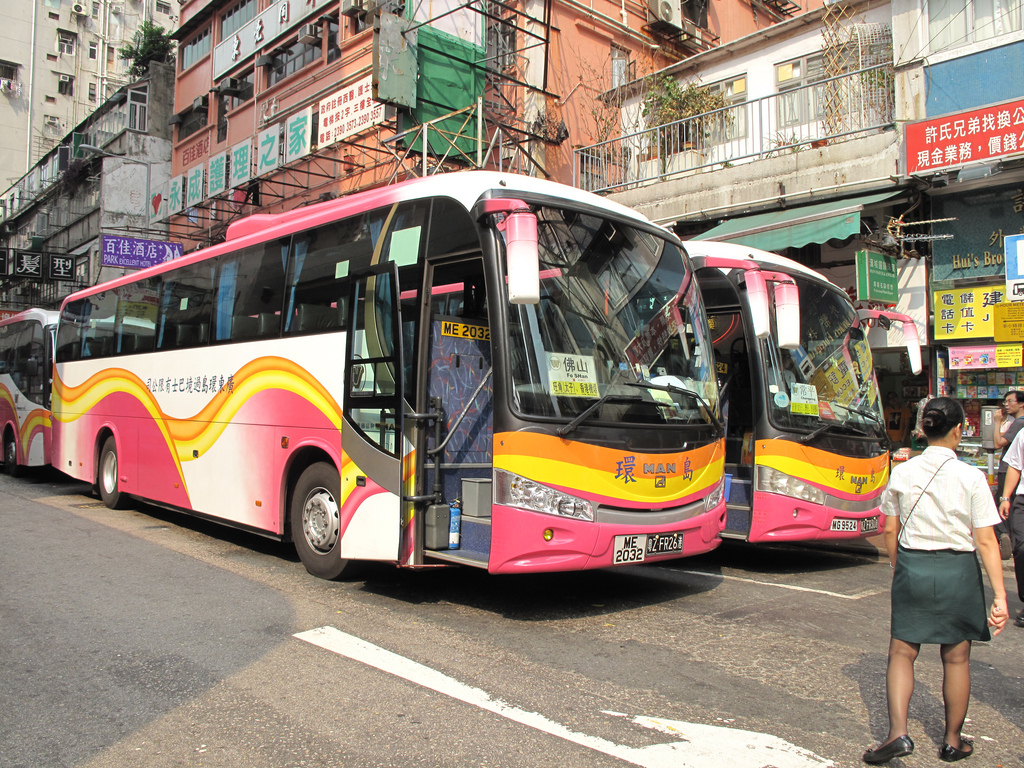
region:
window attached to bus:
[494, 202, 713, 431]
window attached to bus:
[753, 267, 884, 438]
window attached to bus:
[225, 238, 301, 333]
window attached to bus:
[156, 272, 232, 349]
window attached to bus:
[113, 276, 170, 346]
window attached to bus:
[60, 301, 98, 355]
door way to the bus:
[420, 251, 515, 562]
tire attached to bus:
[294, 460, 349, 575]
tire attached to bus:
[80, 437, 132, 510]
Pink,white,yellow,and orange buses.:
[9, 159, 920, 558]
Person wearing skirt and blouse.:
[871, 402, 1005, 766]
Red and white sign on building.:
[900, 95, 1022, 179]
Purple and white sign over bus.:
[93, 229, 177, 275]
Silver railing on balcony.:
[575, 36, 907, 188]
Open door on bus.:
[338, 225, 506, 571]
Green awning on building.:
[692, 182, 917, 263]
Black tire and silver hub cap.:
[287, 457, 355, 585]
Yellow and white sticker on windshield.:
[787, 373, 823, 416]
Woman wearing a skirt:
[883, 535, 1005, 666]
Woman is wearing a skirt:
[867, 528, 1003, 662]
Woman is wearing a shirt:
[863, 443, 1007, 570]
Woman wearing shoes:
[855, 725, 988, 765]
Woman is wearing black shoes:
[854, 713, 991, 765]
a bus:
[140, 188, 728, 566]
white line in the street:
[288, 608, 445, 703]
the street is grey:
[92, 608, 270, 729]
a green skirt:
[892, 552, 979, 635]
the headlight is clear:
[508, 475, 603, 526]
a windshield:
[559, 222, 703, 438]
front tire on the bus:
[285, 459, 346, 561]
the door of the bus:
[351, 272, 408, 551]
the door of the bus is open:
[325, 239, 500, 584]